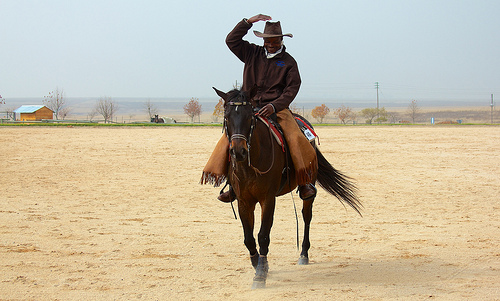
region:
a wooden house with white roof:
[13, 96, 62, 132]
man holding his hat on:
[255, 12, 303, 50]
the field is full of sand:
[13, 137, 225, 287]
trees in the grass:
[321, 95, 456, 128]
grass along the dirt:
[10, 120, 195, 131]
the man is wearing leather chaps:
[195, 105, 318, 191]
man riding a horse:
[216, 0, 316, 270]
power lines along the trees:
[367, 80, 497, 103]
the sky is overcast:
[26, 17, 201, 85]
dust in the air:
[40, 71, 498, 172]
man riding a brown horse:
[192, 8, 387, 293]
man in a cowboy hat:
[204, 11, 354, 91]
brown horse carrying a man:
[196, 82, 377, 289]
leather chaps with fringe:
[268, 103, 327, 203]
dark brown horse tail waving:
[311, 136, 388, 247]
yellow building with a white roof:
[8, 101, 70, 141]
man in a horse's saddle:
[188, 3, 369, 263]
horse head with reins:
[208, 89, 280, 179]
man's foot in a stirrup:
[288, 173, 330, 213]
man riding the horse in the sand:
[69, 8, 439, 288]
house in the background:
[13, 102, 57, 125]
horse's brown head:
[204, 85, 259, 176]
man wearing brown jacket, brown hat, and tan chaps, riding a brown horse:
[178, 9, 375, 295]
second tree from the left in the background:
[86, 95, 121, 129]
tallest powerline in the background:
[365, 70, 389, 132]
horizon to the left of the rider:
[11, 92, 191, 111]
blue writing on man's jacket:
[274, 57, 287, 74]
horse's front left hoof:
[247, 262, 272, 289]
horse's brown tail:
[321, 145, 363, 232]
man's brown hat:
[251, 20, 300, 35]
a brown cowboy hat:
[250, 5, 300, 42]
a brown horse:
[186, 91, 346, 297]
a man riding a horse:
[203, 3, 330, 186]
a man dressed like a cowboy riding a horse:
[218, 14, 325, 214]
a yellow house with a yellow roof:
[10, 92, 70, 126]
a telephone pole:
[368, 75, 394, 122]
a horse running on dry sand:
[103, 2, 442, 298]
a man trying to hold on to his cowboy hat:
[217, 9, 318, 85]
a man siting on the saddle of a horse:
[205, 7, 345, 165]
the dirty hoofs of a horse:
[223, 235, 340, 287]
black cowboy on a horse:
[194, 10, 368, 289]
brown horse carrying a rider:
[206, 86, 381, 291]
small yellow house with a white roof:
[13, 97, 63, 139]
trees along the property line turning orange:
[314, 98, 401, 133]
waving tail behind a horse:
[310, 134, 370, 227]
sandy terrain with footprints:
[46, 164, 112, 286]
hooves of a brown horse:
[225, 237, 300, 293]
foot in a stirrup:
[291, 180, 326, 208]